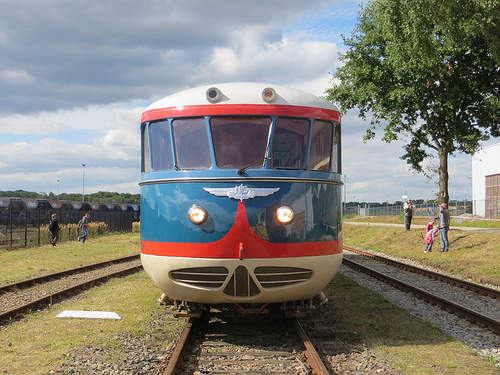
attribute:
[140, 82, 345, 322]
train — blue, large, colorful, red, white,, approaching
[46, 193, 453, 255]
people — running, near train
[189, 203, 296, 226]
lights — on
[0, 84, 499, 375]
train area — active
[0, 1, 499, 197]
clouds — big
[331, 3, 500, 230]
tree — big, green, large, tall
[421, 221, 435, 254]
daughter — small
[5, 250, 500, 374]
grass — rocky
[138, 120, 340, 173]
windows — non-reflective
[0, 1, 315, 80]
sky — overcast, grey, cloudy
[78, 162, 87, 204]
post — far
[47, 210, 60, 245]
boy — leaning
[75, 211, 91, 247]
boy — leaning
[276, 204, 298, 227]
right headlight — on, white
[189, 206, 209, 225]
headlight — on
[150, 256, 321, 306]
design — beige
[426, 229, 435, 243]
jacket — pink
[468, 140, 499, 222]
building — white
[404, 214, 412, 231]
pants — black